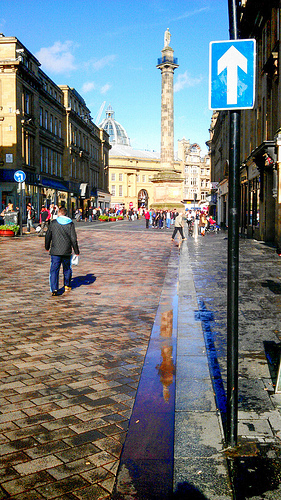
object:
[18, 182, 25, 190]
post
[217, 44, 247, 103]
arrow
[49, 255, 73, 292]
jeans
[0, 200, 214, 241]
many people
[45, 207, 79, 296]
man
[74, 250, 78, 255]
right hand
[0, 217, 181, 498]
street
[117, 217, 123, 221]
planters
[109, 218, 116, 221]
planters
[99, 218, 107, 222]
planters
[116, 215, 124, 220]
plants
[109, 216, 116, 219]
plants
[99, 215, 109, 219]
plants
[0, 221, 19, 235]
plants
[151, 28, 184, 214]
monument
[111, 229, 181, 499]
puddle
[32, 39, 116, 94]
clouds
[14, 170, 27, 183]
round sign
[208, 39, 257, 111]
sign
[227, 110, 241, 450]
post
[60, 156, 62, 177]
window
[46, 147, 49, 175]
window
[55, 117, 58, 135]
window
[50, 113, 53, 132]
window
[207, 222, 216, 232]
wheelchair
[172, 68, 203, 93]
clouds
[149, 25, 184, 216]
tower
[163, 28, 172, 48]
sculpture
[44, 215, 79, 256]
jacket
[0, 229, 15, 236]
planter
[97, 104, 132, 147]
glass dome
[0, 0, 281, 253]
church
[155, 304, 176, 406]
reflection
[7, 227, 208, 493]
street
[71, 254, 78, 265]
bag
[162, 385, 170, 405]
sculpture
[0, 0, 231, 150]
sky